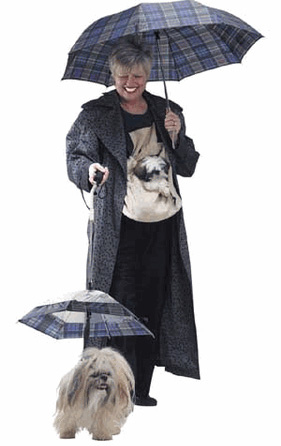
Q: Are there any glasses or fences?
A: No, there are no fences or glasses.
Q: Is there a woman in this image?
A: Yes, there is a woman.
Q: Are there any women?
A: Yes, there is a woman.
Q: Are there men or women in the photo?
A: Yes, there is a woman.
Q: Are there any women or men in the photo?
A: Yes, there is a woman.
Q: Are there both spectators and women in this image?
A: No, there is a woman but no spectators.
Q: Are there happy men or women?
A: Yes, there is a happy woman.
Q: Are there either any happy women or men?
A: Yes, there is a happy woman.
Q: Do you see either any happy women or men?
A: Yes, there is a happy woman.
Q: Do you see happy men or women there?
A: Yes, there is a happy woman.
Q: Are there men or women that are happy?
A: Yes, the woman is happy.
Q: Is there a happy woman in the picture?
A: Yes, there is a happy woman.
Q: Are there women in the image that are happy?
A: Yes, there is a woman that is happy.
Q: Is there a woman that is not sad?
A: Yes, there is a happy woman.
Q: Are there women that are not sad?
A: Yes, there is a happy woman.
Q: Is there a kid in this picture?
A: No, there are no children.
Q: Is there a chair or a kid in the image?
A: No, there are no children or chairs.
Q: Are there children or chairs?
A: No, there are no children or chairs.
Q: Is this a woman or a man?
A: This is a woman.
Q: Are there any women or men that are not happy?
A: No, there is a woman but she is happy.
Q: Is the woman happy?
A: Yes, the woman is happy.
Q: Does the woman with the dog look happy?
A: Yes, the woman is happy.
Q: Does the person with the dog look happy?
A: Yes, the woman is happy.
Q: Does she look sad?
A: No, the woman is happy.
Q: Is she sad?
A: No, the woman is happy.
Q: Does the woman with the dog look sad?
A: No, the woman is happy.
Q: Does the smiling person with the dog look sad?
A: No, the woman is happy.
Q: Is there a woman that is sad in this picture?
A: No, there is a woman but she is happy.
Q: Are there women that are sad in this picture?
A: No, there is a woman but she is happy.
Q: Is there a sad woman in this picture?
A: No, there is a woman but she is happy.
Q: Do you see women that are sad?
A: No, there is a woman but she is happy.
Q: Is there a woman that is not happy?
A: No, there is a woman but she is happy.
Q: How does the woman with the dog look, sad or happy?
A: The woman is happy.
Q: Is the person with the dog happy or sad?
A: The woman is happy.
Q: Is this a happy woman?
A: Yes, this is a happy woman.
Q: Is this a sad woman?
A: No, this is a happy woman.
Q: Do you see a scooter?
A: No, there are no scooters.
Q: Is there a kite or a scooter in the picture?
A: No, there are no scooters or kites.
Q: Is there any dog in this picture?
A: Yes, there is a dog.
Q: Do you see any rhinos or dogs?
A: Yes, there is a dog.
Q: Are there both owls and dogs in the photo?
A: No, there is a dog but no owls.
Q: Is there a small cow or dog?
A: Yes, there is a small dog.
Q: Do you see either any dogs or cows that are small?
A: Yes, the dog is small.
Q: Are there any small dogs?
A: Yes, there is a small dog.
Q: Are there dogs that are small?
A: Yes, there is a dog that is small.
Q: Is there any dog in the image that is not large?
A: Yes, there is a small dog.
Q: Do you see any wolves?
A: No, there are no wolves.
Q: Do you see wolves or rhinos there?
A: No, there are no wolves or rhinos.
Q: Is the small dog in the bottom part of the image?
A: Yes, the dog is in the bottom of the image.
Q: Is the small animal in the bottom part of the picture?
A: Yes, the dog is in the bottom of the image.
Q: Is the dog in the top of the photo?
A: No, the dog is in the bottom of the image.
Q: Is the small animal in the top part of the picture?
A: No, the dog is in the bottom of the image.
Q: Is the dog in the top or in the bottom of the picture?
A: The dog is in the bottom of the image.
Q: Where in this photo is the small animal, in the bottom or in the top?
A: The dog is in the bottom of the image.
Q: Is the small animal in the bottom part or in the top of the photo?
A: The dog is in the bottom of the image.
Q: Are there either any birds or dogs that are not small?
A: No, there is a dog but it is small.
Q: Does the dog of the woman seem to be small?
A: Yes, the dog is small.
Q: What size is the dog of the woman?
A: The dog is small.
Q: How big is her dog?
A: The dog is small.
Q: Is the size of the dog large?
A: No, the dog is small.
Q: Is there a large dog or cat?
A: No, there is a dog but it is small.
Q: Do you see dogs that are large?
A: No, there is a dog but it is small.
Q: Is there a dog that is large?
A: No, there is a dog but it is small.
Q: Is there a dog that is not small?
A: No, there is a dog but it is small.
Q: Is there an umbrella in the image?
A: Yes, there is an umbrella.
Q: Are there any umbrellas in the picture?
A: Yes, there is an umbrella.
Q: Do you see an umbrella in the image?
A: Yes, there is an umbrella.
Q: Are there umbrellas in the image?
A: Yes, there is an umbrella.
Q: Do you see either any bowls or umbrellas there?
A: Yes, there is an umbrella.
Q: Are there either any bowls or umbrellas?
A: Yes, there is an umbrella.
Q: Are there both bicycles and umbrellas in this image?
A: No, there is an umbrella but no bikes.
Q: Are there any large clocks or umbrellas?
A: Yes, there is a large umbrella.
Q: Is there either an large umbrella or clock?
A: Yes, there is a large umbrella.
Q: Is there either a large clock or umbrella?
A: Yes, there is a large umbrella.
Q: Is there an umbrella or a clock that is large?
A: Yes, the umbrella is large.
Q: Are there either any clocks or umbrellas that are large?
A: Yes, the umbrella is large.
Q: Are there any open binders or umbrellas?
A: Yes, there is an open umbrella.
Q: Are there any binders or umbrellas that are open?
A: Yes, the umbrella is open.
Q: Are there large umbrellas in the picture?
A: Yes, there is a large umbrella.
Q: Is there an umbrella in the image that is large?
A: Yes, there is an umbrella that is large.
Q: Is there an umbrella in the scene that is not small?
A: Yes, there is a large umbrella.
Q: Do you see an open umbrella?
A: Yes, there is an open umbrella.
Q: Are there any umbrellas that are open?
A: Yes, there is an umbrella that is open.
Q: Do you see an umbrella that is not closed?
A: Yes, there is a open umbrella.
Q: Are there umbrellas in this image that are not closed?
A: Yes, there is a open umbrella.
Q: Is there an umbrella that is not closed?
A: Yes, there is a open umbrella.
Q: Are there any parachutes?
A: No, there are no parachutes.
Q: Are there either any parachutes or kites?
A: No, there are no parachutes or kites.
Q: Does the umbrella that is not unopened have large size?
A: Yes, the umbrella is large.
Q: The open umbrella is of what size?
A: The umbrella is large.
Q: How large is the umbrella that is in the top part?
A: The umbrella is large.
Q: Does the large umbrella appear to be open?
A: Yes, the umbrella is open.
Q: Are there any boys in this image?
A: No, there are no boys.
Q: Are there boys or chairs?
A: No, there are no boys or chairs.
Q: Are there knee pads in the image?
A: No, there are no knee pads.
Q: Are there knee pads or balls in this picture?
A: No, there are no knee pads or balls.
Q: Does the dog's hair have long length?
A: Yes, the hair is long.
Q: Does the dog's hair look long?
A: Yes, the hair is long.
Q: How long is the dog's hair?
A: The hair is long.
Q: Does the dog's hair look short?
A: No, the hair is long.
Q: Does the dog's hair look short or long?
A: The hair is long.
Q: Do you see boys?
A: No, there are no boys.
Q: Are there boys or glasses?
A: No, there are no boys or glasses.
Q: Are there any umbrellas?
A: Yes, there is an umbrella.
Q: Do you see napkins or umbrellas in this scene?
A: Yes, there is an umbrella.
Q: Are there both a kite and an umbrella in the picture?
A: No, there is an umbrella but no kites.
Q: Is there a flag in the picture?
A: No, there are no flags.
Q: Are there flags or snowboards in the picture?
A: No, there are no flags or snowboards.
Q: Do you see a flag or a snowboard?
A: No, there are no flags or snowboards.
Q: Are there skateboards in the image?
A: No, there are no skateboards.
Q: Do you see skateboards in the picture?
A: No, there are no skateboards.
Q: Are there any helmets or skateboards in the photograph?
A: No, there are no skateboards or helmets.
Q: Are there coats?
A: Yes, there is a coat.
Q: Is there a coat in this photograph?
A: Yes, there is a coat.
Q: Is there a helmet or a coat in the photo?
A: Yes, there is a coat.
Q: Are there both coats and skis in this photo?
A: No, there is a coat but no skis.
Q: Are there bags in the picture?
A: No, there are no bags.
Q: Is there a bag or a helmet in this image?
A: No, there are no bags or helmets.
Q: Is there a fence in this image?
A: No, there are no fences.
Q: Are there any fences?
A: No, there are no fences.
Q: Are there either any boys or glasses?
A: No, there are no boys or glasses.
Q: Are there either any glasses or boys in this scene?
A: No, there are no boys or glasses.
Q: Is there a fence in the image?
A: No, there are no fences.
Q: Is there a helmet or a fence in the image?
A: No, there are no fences or helmets.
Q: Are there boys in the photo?
A: No, there are no boys.